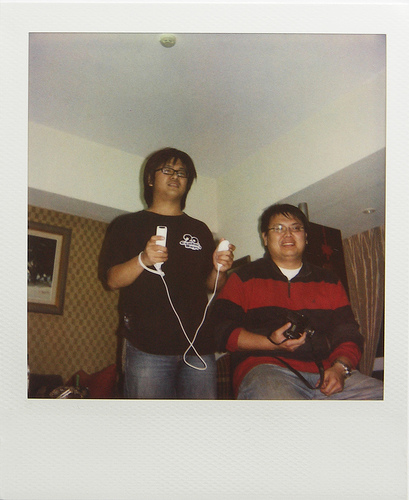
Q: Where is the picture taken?
A: In a house.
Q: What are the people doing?
A: Playing video games.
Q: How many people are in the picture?
A: Two.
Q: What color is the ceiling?
A: White.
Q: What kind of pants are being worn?
A: Blue jeans.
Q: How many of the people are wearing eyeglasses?
A: Two.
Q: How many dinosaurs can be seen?
A: None.